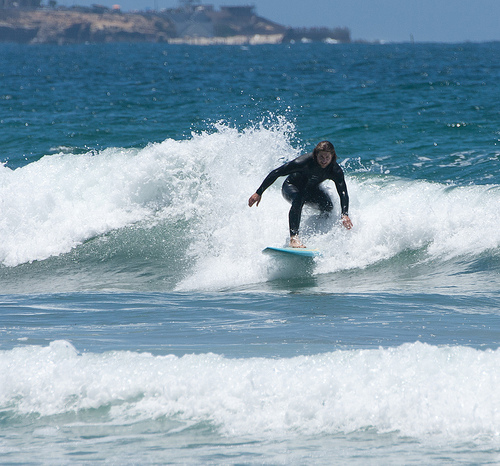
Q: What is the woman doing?
A: Surfing.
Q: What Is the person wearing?
A: A black wetsuit.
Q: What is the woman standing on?
A: A surfboard.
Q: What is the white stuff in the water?
A: Waves.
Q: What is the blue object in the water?
A: A surfboard.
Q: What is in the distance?
A: A land formation.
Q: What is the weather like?
A: Clear sky.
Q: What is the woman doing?
A: Crouching.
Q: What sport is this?
A: Surfing.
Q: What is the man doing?
A: Surfing.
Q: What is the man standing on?
A: Surfboard.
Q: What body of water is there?
A: Ocean.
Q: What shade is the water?
A: Blue.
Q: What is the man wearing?
A: Wetsuit.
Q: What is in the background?
A: Mountains.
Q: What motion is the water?
A: Wavy.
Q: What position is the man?
A: Kneeling.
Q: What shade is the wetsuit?
A: Black.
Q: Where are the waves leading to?
A: Beach.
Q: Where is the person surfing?
A: Ocean.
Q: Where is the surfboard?
A: On the water.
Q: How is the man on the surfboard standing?
A: Crouched.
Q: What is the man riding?
A: Surfboard.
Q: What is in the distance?
A: Shoreline.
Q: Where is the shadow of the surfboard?
A: On the water.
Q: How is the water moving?
A: In a wave.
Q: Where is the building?
A: On the shore.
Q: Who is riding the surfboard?
A: The man..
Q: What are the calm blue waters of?
A: The ocean.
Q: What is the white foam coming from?
A: A wave.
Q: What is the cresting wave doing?
A: Rolling over on itself.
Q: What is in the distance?
A: A hilly island.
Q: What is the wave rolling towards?
A: The beach.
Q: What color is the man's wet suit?
A: Black.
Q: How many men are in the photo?
A: 1.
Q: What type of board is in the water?
A: A surf board.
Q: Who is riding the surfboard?
A: The man.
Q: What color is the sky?
A: Blue.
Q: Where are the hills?
A: Far in the background.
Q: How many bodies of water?
A: 1.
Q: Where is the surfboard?
A: In the water.